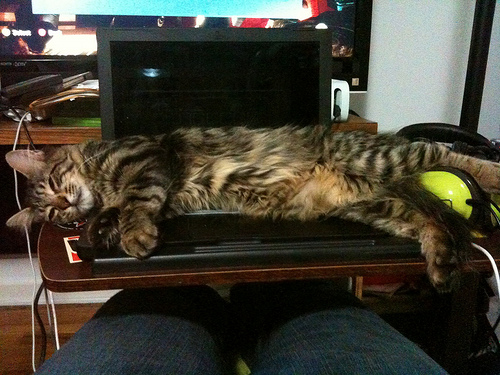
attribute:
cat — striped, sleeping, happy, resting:
[23, 122, 463, 248]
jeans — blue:
[70, 301, 411, 374]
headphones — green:
[421, 175, 490, 225]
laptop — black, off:
[89, 25, 350, 128]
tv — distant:
[21, 26, 56, 49]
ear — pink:
[11, 132, 55, 187]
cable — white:
[472, 244, 500, 356]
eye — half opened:
[38, 167, 66, 192]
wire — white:
[27, 251, 44, 288]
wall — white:
[412, 63, 438, 111]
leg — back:
[342, 136, 497, 180]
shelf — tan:
[42, 125, 86, 149]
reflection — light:
[139, 55, 167, 97]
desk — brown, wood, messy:
[1, 59, 72, 129]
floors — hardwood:
[74, 309, 94, 322]